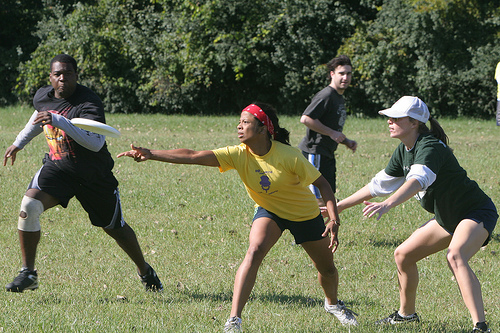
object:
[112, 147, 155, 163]
hand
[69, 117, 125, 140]
frisbee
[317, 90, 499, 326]
she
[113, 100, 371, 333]
she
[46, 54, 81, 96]
head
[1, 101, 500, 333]
field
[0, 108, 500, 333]
ground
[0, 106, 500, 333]
grass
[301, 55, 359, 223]
body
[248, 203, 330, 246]
shorts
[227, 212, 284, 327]
leg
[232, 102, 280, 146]
head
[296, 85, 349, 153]
shirt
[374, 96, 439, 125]
cap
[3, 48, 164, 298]
man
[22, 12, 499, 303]
park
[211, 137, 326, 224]
shirt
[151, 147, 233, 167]
arm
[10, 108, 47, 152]
arm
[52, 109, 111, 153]
arm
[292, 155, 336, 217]
arm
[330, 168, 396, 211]
arm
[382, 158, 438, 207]
arm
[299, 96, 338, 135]
arm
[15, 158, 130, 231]
shorts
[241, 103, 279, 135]
bandana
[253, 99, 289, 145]
hair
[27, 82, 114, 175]
shirt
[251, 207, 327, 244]
pant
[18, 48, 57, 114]
trees